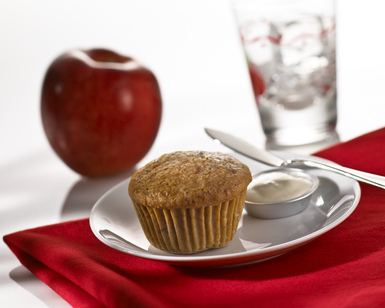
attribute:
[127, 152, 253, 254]
muffin — brown, bran, delicious, buttered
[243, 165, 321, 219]
container — butter, round, silver, crem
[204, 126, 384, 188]
knife — silver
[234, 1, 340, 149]
glass — water, clear, icy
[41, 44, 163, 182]
apple — red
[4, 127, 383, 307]
napkin — red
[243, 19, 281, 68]
ice — clear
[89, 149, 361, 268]
plate — round, white, shiny